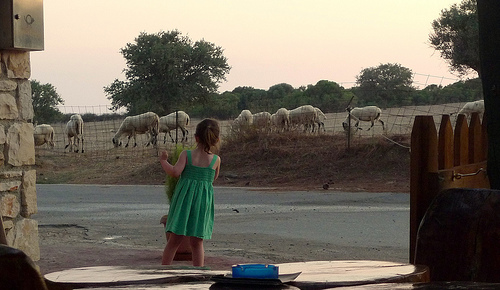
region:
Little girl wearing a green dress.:
[138, 116, 240, 263]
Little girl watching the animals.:
[151, 113, 232, 265]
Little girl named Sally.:
[159, 105, 233, 266]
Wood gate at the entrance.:
[398, 102, 491, 198]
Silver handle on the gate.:
[446, 160, 486, 189]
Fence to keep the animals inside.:
[52, 98, 180, 157]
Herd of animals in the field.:
[230, 95, 330, 142]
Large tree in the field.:
[105, 27, 230, 110]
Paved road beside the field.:
[257, 194, 398, 227]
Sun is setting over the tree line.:
[246, 14, 361, 85]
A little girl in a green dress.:
[158, 118, 224, 270]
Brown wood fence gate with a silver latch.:
[407, 110, 490, 265]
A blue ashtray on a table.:
[229, 261, 280, 280]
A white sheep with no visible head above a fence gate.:
[458, 98, 485, 115]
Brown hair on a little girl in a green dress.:
[192, 120, 222, 155]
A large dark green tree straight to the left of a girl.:
[103, 28, 233, 122]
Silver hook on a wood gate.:
[453, 166, 488, 180]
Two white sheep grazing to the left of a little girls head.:
[111, 110, 192, 147]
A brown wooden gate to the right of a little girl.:
[408, 110, 493, 264]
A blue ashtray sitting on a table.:
[230, 260, 280, 283]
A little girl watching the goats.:
[151, 118, 226, 244]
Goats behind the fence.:
[105, 110, 313, 139]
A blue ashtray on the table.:
[226, 245, 277, 277]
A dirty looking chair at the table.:
[413, 175, 494, 276]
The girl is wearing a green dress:
[176, 148, 218, 250]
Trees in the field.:
[128, 19, 351, 97]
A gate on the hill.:
[76, 110, 412, 144]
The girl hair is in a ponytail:
[193, 113, 220, 140]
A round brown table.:
[83, 246, 405, 288]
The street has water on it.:
[236, 184, 410, 244]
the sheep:
[227, 108, 321, 128]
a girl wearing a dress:
[167, 163, 217, 238]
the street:
[260, 188, 366, 240]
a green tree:
[123, 38, 223, 110]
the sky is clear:
[250, 9, 374, 60]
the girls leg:
[162, 236, 181, 264]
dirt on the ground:
[232, 230, 284, 263]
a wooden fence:
[405, 121, 465, 156]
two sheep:
[36, 112, 84, 149]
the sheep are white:
[228, 101, 332, 138]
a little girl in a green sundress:
[157, 115, 222, 266]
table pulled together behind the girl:
[42, 258, 497, 288]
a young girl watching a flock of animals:
[35, 102, 412, 263]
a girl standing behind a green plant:
[155, 111, 220, 261]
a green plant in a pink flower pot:
[156, 140, 191, 257]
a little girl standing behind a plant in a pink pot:
[157, 117, 220, 263]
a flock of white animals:
[35, 103, 387, 154]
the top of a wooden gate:
[408, 109, 485, 186]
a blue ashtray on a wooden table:
[230, 263, 280, 279]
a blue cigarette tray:
[229, 260, 279, 279]